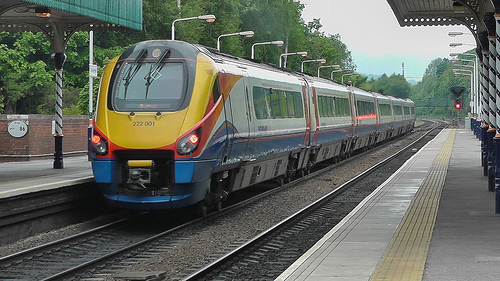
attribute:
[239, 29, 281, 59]
pole — light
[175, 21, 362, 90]
lights — street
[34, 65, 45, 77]
leaf — green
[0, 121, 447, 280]
tracks — black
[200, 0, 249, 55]
tree — old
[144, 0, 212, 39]
tree — old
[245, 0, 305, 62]
tree — old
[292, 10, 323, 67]
tree — old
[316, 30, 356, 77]
tree — old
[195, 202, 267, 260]
rocks — small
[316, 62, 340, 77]
pole — light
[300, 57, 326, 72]
pole — light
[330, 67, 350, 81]
pole — light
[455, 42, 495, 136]
pole — light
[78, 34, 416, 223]
train — long